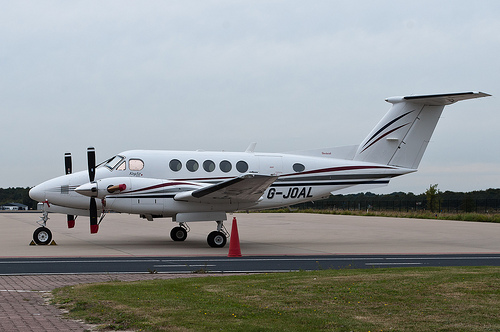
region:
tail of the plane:
[360, 80, 454, 168]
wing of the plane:
[197, 167, 269, 205]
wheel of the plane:
[210, 230, 225, 252]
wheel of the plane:
[157, 218, 190, 238]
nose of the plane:
[13, 168, 66, 207]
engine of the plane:
[62, 178, 117, 195]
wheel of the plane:
[31, 225, 51, 240]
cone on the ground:
[228, 215, 246, 259]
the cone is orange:
[230, 223, 242, 253]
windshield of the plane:
[105, 154, 134, 166]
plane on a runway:
[24, 77, 498, 265]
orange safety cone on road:
[217, 212, 251, 261]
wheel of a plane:
[17, 224, 72, 256]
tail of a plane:
[366, 79, 491, 172]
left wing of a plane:
[182, 171, 277, 208]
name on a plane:
[266, 184, 319, 204]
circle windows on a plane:
[166, 153, 249, 176]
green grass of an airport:
[244, 281, 470, 320]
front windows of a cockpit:
[103, 153, 125, 171]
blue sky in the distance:
[66, 42, 388, 120]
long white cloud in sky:
[216, 30, 478, 62]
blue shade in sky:
[241, 76, 268, 96]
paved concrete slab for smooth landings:
[330, 216, 387, 244]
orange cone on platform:
[226, 217, 248, 256]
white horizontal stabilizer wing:
[383, 90, 490, 101]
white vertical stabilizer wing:
[353, 103, 450, 166]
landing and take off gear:
[32, 217, 225, 250]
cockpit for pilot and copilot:
[106, 152, 141, 172]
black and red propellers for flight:
[82, 145, 102, 235]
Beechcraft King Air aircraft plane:
[28, 89, 490, 245]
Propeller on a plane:
[74, 142, 110, 246]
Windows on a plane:
[103, 147, 150, 177]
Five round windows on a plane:
[164, 154, 256, 179]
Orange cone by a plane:
[225, 211, 256, 261]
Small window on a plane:
[289, 157, 306, 184]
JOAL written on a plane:
[283, 182, 319, 202]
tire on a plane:
[28, 221, 58, 256]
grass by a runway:
[88, 269, 292, 326]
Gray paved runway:
[266, 217, 417, 263]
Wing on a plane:
[170, 171, 282, 222]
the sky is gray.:
[1, 0, 497, 183]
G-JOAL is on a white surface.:
[265, 185, 317, 204]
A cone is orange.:
[226, 216, 243, 261]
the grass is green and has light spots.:
[55, 265, 499, 327]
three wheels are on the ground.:
[33, 225, 227, 247]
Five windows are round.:
[166, 159, 251, 173]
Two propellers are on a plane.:
[60, 143, 103, 239]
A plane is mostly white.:
[28, 87, 490, 257]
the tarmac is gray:
[0, 211, 498, 255]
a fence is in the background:
[290, 197, 499, 214]